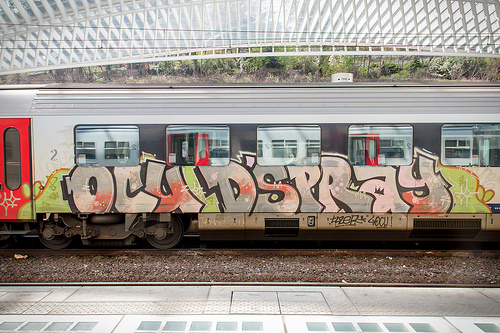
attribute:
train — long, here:
[1, 84, 499, 245]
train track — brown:
[2, 243, 494, 258]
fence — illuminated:
[3, 5, 499, 74]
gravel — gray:
[92, 254, 173, 276]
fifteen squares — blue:
[3, 314, 499, 332]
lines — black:
[107, 310, 132, 332]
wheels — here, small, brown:
[34, 209, 193, 252]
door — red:
[0, 107, 40, 220]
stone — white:
[111, 311, 290, 332]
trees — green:
[187, 63, 354, 74]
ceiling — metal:
[6, 1, 500, 72]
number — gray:
[50, 147, 64, 164]